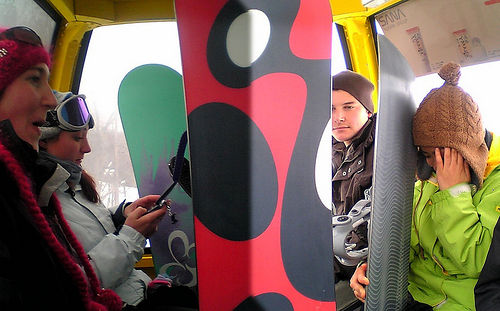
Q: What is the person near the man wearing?
A: The person is wearing a jacket.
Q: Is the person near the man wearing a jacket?
A: Yes, the person is wearing a jacket.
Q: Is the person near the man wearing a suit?
A: No, the person is wearing a jacket.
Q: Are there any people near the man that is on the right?
A: Yes, there is a person near the man.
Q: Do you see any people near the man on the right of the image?
A: Yes, there is a person near the man.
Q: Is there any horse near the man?
A: No, there is a person near the man.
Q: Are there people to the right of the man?
A: Yes, there is a person to the right of the man.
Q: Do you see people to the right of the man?
A: Yes, there is a person to the right of the man.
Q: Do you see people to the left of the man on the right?
A: No, the person is to the right of the man.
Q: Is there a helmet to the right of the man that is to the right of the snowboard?
A: No, there is a person to the right of the man.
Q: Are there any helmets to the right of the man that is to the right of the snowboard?
A: No, there is a person to the right of the man.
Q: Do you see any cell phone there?
A: Yes, there is a cell phone.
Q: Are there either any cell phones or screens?
A: Yes, there is a cell phone.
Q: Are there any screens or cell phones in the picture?
A: Yes, there is a cell phone.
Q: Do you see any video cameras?
A: No, there are no video cameras.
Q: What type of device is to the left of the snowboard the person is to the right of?
A: The device is a cell phone.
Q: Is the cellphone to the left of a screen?
A: No, the cellphone is to the left of the snowboard.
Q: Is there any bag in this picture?
A: No, there are no bags.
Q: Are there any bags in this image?
A: No, there are no bags.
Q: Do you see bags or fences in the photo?
A: No, there are no bags or fences.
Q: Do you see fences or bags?
A: No, there are no bags or fences.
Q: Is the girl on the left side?
A: Yes, the girl is on the left of the image.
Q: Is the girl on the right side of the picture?
A: No, the girl is on the left of the image.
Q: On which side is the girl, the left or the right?
A: The girl is on the left of the image.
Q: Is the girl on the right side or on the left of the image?
A: The girl is on the left of the image.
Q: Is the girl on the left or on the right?
A: The girl is on the left of the image.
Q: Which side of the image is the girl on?
A: The girl is on the left of the image.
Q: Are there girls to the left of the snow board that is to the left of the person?
A: Yes, there is a girl to the left of the snow board.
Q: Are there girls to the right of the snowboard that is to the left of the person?
A: No, the girl is to the left of the snowboard.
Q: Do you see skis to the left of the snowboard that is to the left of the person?
A: No, there is a girl to the left of the snowboard.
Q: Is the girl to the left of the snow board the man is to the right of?
A: Yes, the girl is to the left of the snowboard.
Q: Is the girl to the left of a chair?
A: No, the girl is to the left of the snowboard.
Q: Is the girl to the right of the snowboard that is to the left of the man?
A: No, the girl is to the left of the snow board.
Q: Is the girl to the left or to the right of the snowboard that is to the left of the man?
A: The girl is to the left of the snow board.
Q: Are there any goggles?
A: Yes, there are goggles.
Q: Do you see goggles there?
A: Yes, there are goggles.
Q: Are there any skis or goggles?
A: Yes, there are goggles.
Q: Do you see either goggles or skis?
A: Yes, there are goggles.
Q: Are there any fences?
A: No, there are no fences.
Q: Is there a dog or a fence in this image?
A: No, there are no fences or dogs.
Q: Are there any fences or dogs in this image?
A: No, there are no fences or dogs.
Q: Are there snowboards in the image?
A: Yes, there is a snowboard.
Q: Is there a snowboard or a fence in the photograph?
A: Yes, there is a snowboard.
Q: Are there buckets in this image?
A: No, there are no buckets.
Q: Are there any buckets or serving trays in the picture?
A: No, there are no buckets or serving trays.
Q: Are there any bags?
A: No, there are no bags.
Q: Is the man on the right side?
A: Yes, the man is on the right of the image.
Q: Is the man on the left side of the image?
A: No, the man is on the right of the image.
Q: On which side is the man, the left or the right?
A: The man is on the right of the image.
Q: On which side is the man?
A: The man is on the right of the image.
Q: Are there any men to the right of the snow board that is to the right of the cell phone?
A: Yes, there is a man to the right of the snowboard.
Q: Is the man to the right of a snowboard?
A: Yes, the man is to the right of a snowboard.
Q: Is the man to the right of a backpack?
A: No, the man is to the right of a snowboard.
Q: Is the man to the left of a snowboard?
A: No, the man is to the right of a snowboard.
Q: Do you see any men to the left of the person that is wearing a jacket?
A: Yes, there is a man to the left of the person.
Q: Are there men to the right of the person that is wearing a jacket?
A: No, the man is to the left of the person.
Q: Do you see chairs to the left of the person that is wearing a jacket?
A: No, there is a man to the left of the person.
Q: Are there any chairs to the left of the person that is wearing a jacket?
A: No, there is a man to the left of the person.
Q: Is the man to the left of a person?
A: Yes, the man is to the left of a person.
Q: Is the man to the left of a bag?
A: No, the man is to the left of a person.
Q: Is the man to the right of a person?
A: No, the man is to the left of a person.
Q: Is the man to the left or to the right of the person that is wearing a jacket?
A: The man is to the left of the person.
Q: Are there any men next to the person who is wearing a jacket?
A: Yes, there is a man next to the person.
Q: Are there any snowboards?
A: Yes, there is a snowboard.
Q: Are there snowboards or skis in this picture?
A: Yes, there is a snowboard.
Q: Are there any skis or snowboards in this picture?
A: Yes, there is a snowboard.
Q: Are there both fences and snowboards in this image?
A: No, there is a snowboard but no fences.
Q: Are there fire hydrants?
A: No, there are no fire hydrants.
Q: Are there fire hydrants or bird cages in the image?
A: No, there are no fire hydrants or bird cages.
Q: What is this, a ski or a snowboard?
A: This is a snowboard.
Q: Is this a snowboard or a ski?
A: This is a snowboard.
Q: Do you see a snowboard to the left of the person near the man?
A: Yes, there is a snowboard to the left of the person.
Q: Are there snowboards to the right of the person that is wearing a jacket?
A: No, the snowboard is to the left of the person.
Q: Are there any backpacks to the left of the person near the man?
A: No, there is a snowboard to the left of the person.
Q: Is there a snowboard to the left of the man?
A: Yes, there is a snowboard to the left of the man.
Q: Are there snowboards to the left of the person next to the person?
A: Yes, there is a snowboard to the left of the man.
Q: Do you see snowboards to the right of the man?
A: No, the snowboard is to the left of the man.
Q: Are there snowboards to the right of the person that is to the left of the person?
A: No, the snowboard is to the left of the man.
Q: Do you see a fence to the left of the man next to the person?
A: No, there is a snowboard to the left of the man.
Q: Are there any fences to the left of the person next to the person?
A: No, there is a snowboard to the left of the man.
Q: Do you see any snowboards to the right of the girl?
A: Yes, there is a snowboard to the right of the girl.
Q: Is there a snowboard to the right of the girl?
A: Yes, there is a snowboard to the right of the girl.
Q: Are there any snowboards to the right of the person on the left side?
A: Yes, there is a snowboard to the right of the girl.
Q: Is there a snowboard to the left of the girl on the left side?
A: No, the snowboard is to the right of the girl.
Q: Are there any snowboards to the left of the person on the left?
A: No, the snowboard is to the right of the girl.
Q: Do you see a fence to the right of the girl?
A: No, there is a snowboard to the right of the girl.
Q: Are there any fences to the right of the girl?
A: No, there is a snowboard to the right of the girl.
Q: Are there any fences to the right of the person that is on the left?
A: No, there is a snowboard to the right of the girl.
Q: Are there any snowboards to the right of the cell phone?
A: Yes, there is a snowboard to the right of the cell phone.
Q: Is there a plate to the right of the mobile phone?
A: No, there is a snowboard to the right of the mobile phone.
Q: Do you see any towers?
A: No, there are no towers.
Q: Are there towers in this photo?
A: No, there are no towers.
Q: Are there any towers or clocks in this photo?
A: No, there are no towers or clocks.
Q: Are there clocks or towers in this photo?
A: No, there are no towers or clocks.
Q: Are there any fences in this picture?
A: No, there are no fences.